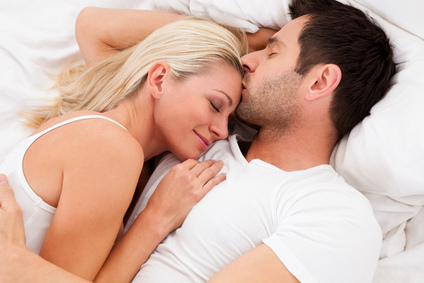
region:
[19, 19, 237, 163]
A woman with blonde hair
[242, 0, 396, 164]
A man black hair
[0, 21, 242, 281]
A woman laying down smiling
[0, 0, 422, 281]
Man lying down in bed with a woman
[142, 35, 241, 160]
Woman smiles with her eyes closed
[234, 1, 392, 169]
Man kissing the forehead of the woman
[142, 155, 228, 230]
The woman's hand on the man's chest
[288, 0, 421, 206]
Mans head lying on a white pillow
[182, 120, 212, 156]
The woman's pink lips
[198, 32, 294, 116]
The man and woman's eyes are closed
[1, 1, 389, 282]
couple laying in bed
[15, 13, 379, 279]
female with blonde hair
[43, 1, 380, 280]
man with brown hair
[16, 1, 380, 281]
man with white tshirt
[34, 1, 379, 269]
man with scruffy beard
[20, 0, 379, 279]
female with pink lips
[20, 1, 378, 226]
blonde wearing white tank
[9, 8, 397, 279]
man kissing woman in bed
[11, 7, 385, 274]
woman with smile on face in bed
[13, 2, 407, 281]
people lying in bed with white bedding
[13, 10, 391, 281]
Happy, snuggling couple.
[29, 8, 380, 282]
Man and woman, lying in bed together, wearing white.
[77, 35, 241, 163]
Blonde head of smiling woman in repose.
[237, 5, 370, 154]
Brown-haired head of sleeping man, featuring hawk nose and five 'o clock shadow.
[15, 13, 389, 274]
Woman in white lingerie, resting head on the chest of man in white tee-shirt.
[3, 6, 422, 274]
White linen on bed, composing backdrop for sleeping couple, also in white.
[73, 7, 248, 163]
Man's right elbow, making pillow for woman's head.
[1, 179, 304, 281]
Couple using his left arm and her right arm to enfold and touch each other as they sleep.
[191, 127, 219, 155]
Pink lipstick on woman's smiling mouth.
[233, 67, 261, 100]
Man's lips pressed in kiss against woman's brow.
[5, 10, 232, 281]
an attractive blonde woman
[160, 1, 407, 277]
a dark haired man sleeping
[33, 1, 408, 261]
a couple napping in bed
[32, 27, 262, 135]
dark roots of blonde hair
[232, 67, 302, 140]
a dark scruffy beard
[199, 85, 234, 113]
light brown eye shadow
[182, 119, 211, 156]
a woman's smiling mouth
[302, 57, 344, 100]
a white person's ear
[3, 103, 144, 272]
a white tank top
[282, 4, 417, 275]
plump white pillows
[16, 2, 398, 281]
a couple relaxing in bed together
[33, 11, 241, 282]
a woman with blond hair laying in bed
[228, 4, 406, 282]
a man with black hair laying in bed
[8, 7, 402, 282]
a man and woman both wearing white tops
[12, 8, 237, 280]
a woman wearing a white tank top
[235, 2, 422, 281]
a man wearing a white t-shirt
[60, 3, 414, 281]
a couple cuddling in a bed with white sheets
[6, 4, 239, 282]
a content woman with her eyes closed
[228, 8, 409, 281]
a man with his eyes closed and head on a white pillow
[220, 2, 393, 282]
a man with dark stubble